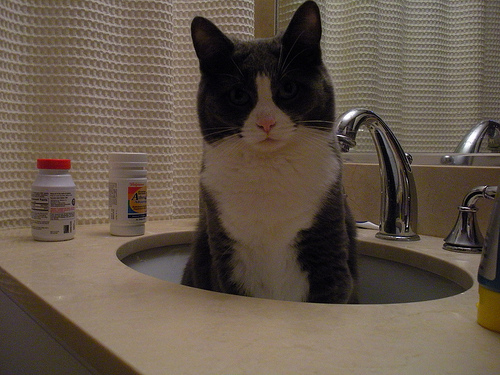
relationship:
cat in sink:
[183, 12, 359, 285] [112, 215, 455, 317]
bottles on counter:
[28, 141, 162, 244] [20, 202, 214, 341]